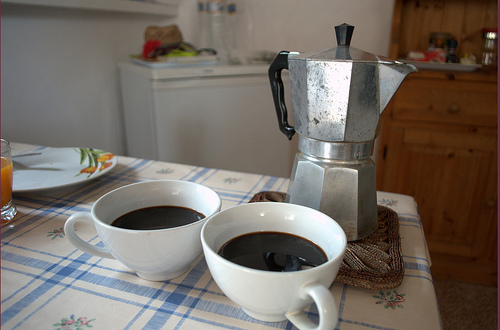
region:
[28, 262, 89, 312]
the table cloth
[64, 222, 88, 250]
a handle on the cup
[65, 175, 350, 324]
two cups on the table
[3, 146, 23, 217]
a glass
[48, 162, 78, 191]
a plate on the table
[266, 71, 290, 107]
a black handle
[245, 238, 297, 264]
brown liquid in the cup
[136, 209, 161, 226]
the liquid is brown in the cup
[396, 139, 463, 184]
a wooden cabinet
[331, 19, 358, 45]
the top is black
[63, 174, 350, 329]
Two cups of coffee on the table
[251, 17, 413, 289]
Espresso coffee maker on a hot plate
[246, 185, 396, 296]
Hot plate under the espresso maker.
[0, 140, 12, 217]
Glass of juice on the table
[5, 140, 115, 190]
White plate with flower motif.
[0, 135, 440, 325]
Blue and white checkered tablecloth with flowers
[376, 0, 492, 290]
Blurry wooden cabinet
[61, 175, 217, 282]
Espresso in a coffee cup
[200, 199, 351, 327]
Espresso in a coffee cup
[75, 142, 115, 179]
Yellow flowers on the plate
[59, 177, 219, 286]
a white mug of coffee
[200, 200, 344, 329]
a white mug of coffee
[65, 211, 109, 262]
a white mug handle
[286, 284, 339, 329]
a white mug handle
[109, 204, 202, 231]
very dark coffee in the cup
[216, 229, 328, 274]
very dark coffee in the cup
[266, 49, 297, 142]
the black handle of the pot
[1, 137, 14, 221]
the clear drinking class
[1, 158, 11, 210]
orange juice in the glass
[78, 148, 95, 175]
the orange flower on the plate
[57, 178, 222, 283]
coffee in a white coffee cup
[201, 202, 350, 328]
coffee in a white coffee cup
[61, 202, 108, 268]
the handle of a coffee cup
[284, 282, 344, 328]
the handle of a coffee cup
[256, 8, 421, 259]
a metal coffee pot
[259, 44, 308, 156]
the handle of a coffee pot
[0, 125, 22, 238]
orange juice in a glass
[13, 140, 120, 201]
a white plate with a flower design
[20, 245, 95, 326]
a white and blue table cloth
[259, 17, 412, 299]
a metal hot plate with a coffee pot on it